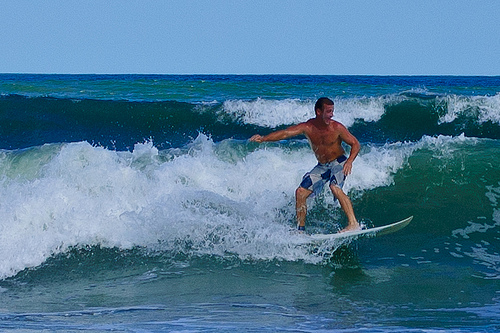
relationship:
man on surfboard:
[248, 98, 363, 235] [312, 215, 414, 241]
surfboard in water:
[312, 215, 414, 241] [0, 72, 500, 333]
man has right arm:
[248, 98, 363, 235] [249, 122, 309, 144]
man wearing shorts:
[248, 98, 363, 235] [299, 153, 352, 193]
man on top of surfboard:
[248, 98, 363, 235] [312, 215, 414, 241]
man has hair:
[248, 98, 363, 235] [315, 97, 333, 111]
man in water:
[248, 98, 363, 235] [0, 72, 500, 333]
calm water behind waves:
[1, 73, 499, 98] [0, 85, 500, 285]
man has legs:
[248, 98, 363, 235] [328, 169, 361, 236]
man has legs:
[248, 98, 363, 235] [296, 154, 360, 235]